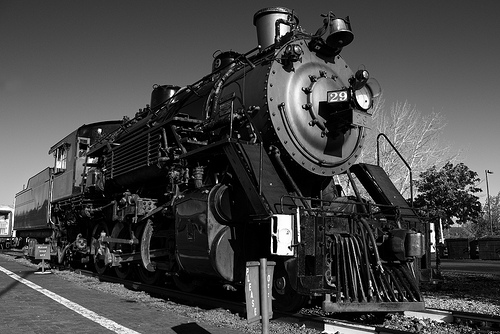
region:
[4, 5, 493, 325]
old black and white of a train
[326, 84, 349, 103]
white numerals for train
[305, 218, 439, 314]
cow pusher on front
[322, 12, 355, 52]
bell for the train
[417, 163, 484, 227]
leaves on tree in the back ground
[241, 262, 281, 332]
sign with the word please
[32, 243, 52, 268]
sign with writing on it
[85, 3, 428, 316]
trains engine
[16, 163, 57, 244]
caboose of the train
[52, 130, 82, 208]
place where the engineer usually stands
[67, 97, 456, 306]
a black vintage train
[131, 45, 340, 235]
a black vintage train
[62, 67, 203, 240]
a black vintage train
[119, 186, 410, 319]
a black vintage train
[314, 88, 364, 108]
the number is 29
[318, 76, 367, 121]
the number is 29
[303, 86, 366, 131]
the number is 29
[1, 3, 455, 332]
a locomotive on a railroad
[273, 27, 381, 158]
number 29 in front a locomotive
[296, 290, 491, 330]
gravel on railroad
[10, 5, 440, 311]
locomotive is black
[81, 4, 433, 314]
engine of locomotive is black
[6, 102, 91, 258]
cars behind the engine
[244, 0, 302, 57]
smoke stack on top of locomotive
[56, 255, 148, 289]
wheels on rails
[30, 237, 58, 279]
a sign on side of locomotive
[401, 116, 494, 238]
trees on right side of locomotive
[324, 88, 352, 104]
the number 29 on train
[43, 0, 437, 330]
black classic train engine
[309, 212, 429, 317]
train engine's cow catcher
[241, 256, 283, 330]
sign that reads 'please off'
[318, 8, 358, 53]
bell on front of train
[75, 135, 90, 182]
door to engineer's area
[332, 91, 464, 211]
tree with no leaves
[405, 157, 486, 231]
tree with many leaves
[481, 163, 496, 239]
street lamp in background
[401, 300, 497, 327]
one portion of train track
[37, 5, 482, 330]
an old train engine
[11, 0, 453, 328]
antique train engine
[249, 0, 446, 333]
a train engine with the number 29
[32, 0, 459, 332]
an old train engine on the tracks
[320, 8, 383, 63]
a bell on a train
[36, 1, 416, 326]
the train engine is black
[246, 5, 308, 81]
the chimney of a train engine car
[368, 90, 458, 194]
a tree with no leaves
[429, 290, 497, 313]
gravel on the ground next to the tracks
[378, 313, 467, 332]
gravel on the train tracks